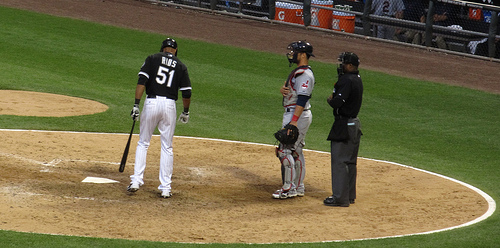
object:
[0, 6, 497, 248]
grass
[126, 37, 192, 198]
baseball player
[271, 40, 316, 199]
baseball player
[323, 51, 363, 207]
baseball player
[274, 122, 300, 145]
catchers glove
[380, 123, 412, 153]
ground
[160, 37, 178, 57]
helmet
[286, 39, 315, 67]
helmet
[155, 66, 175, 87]
number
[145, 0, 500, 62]
fence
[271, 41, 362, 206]
players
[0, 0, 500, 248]
baseball field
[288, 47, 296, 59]
mask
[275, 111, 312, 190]
pants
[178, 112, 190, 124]
batting glove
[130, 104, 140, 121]
batting glove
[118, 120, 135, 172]
baseball bat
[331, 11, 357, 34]
cooler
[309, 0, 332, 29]
cooler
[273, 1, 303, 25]
cooler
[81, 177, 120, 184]
base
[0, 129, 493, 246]
dirt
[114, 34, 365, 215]
baseball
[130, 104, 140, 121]
hand